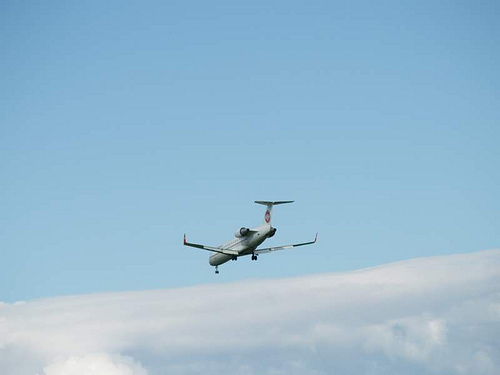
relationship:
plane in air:
[183, 200, 318, 275] [2, 0, 499, 274]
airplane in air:
[183, 200, 318, 275] [2, 0, 499, 274]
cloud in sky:
[1, 249, 498, 374] [2, 0, 499, 274]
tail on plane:
[254, 199, 294, 224] [183, 200, 318, 275]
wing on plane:
[183, 232, 240, 261] [183, 200, 318, 275]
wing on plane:
[254, 234, 319, 258] [183, 200, 318, 275]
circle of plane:
[263, 213, 271, 224] [183, 200, 318, 275]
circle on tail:
[263, 213, 271, 224] [254, 199, 294, 224]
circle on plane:
[263, 213, 271, 224] [183, 200, 318, 275]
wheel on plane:
[251, 253, 258, 261] [183, 200, 318, 275]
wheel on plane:
[214, 268, 220, 274] [183, 200, 318, 275]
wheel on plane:
[230, 255, 238, 262] [183, 200, 318, 275]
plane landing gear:
[183, 200, 318, 275] [215, 250, 259, 276]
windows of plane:
[209, 238, 240, 263] [183, 200, 318, 275]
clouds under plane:
[1, 249, 498, 374] [183, 200, 318, 275]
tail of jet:
[254, 199, 294, 224] [183, 200, 318, 275]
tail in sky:
[254, 199, 294, 224] [2, 0, 499, 274]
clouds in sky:
[1, 249, 498, 374] [2, 0, 499, 274]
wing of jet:
[183, 232, 240, 261] [183, 200, 318, 275]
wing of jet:
[254, 234, 319, 258] [183, 200, 318, 275]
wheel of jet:
[251, 253, 258, 261] [183, 200, 318, 275]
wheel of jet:
[214, 268, 220, 274] [183, 200, 318, 275]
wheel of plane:
[230, 255, 238, 262] [183, 200, 318, 275]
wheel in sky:
[251, 253, 258, 261] [2, 0, 499, 274]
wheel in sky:
[214, 268, 220, 274] [2, 0, 499, 274]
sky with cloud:
[2, 0, 499, 274] [1, 249, 498, 374]